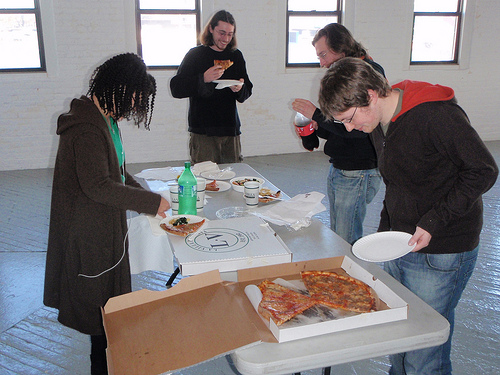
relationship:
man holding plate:
[170, 10, 253, 165] [212, 79, 244, 86]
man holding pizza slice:
[170, 10, 253, 165] [213, 59, 234, 71]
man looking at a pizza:
[318, 56, 499, 374] [256, 270, 380, 326]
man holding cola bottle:
[291, 23, 386, 247] [294, 111, 320, 151]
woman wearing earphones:
[43, 52, 171, 374] [78, 117, 132, 279]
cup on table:
[243, 180, 262, 208] [140, 162, 450, 374]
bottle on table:
[177, 161, 198, 216] [140, 162, 450, 374]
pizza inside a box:
[256, 270, 380, 326] [100, 254, 409, 374]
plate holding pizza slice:
[159, 214, 208, 237] [160, 219, 206, 237]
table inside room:
[140, 162, 450, 374] [1, 1, 500, 375]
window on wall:
[1, 1, 47, 74] [0, 0, 499, 172]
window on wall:
[134, 0, 201, 70] [0, 0, 499, 172]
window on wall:
[285, 0, 342, 68] [0, 0, 499, 172]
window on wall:
[410, 0, 464, 65] [0, 0, 499, 172]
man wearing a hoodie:
[318, 56, 499, 374] [367, 79, 499, 255]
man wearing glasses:
[170, 10, 253, 165] [212, 26, 236, 39]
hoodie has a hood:
[367, 79, 499, 255] [375, 79, 458, 138]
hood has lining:
[375, 79, 458, 138] [390, 79, 455, 122]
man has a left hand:
[318, 56, 499, 374] [408, 226, 432, 253]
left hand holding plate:
[408, 226, 432, 253] [351, 230, 417, 263]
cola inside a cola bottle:
[299, 129, 319, 152] [294, 111, 320, 151]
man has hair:
[170, 10, 253, 165] [199, 10, 236, 50]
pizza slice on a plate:
[160, 219, 206, 237] [159, 214, 208, 237]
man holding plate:
[318, 56, 499, 374] [351, 230, 417, 263]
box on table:
[100, 254, 409, 374] [140, 162, 450, 374]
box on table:
[166, 215, 294, 277] [140, 162, 450, 374]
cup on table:
[196, 177, 207, 211] [140, 162, 450, 374]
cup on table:
[167, 183, 179, 216] [140, 162, 450, 374]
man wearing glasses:
[318, 56, 499, 374] [333, 106, 358, 124]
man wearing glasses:
[291, 23, 386, 247] [316, 47, 331, 59]